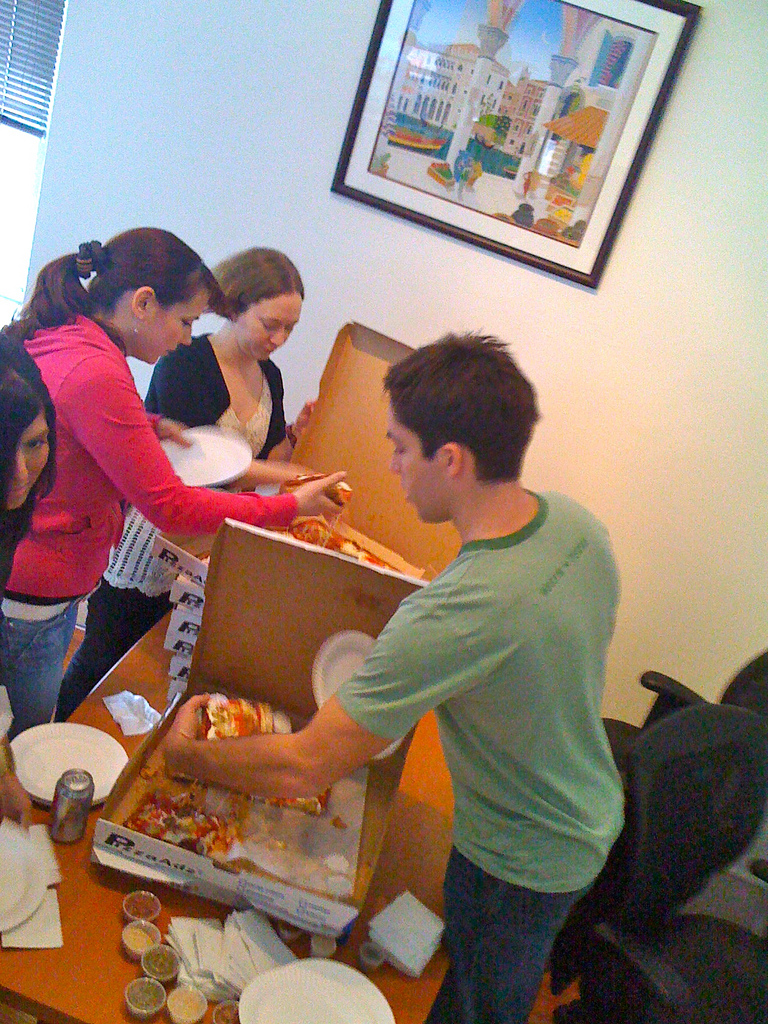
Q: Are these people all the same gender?
A: No, they are both male and female.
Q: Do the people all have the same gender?
A: No, they are both male and female.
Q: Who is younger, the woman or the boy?
A: The boy is younger than the woman.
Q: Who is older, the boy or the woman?
A: The woman is older than the boy.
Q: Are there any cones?
A: No, there are no cones.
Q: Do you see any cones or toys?
A: No, there are no cones or toys.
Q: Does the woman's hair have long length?
A: Yes, the hair is long.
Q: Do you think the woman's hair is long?
A: Yes, the hair is long.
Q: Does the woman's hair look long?
A: Yes, the hair is long.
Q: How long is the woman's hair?
A: The hair is long.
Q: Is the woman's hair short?
A: No, the hair is long.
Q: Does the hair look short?
A: No, the hair is long.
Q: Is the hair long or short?
A: The hair is long.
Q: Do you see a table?
A: Yes, there is a table.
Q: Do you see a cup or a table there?
A: Yes, there is a table.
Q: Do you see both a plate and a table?
A: Yes, there are both a table and a plate.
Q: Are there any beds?
A: No, there are no beds.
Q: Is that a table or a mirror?
A: That is a table.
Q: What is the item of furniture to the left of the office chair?
A: The piece of furniture is a table.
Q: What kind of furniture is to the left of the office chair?
A: The piece of furniture is a table.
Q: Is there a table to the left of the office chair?
A: Yes, there is a table to the left of the office chair.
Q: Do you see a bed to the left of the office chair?
A: No, there is a table to the left of the office chair.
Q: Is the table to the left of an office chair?
A: Yes, the table is to the left of an office chair.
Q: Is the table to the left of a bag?
A: No, the table is to the left of an office chair.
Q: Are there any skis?
A: No, there are no skis.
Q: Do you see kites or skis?
A: No, there are no skis or kites.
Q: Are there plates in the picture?
A: Yes, there is a plate.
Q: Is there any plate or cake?
A: Yes, there is a plate.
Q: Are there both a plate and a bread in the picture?
A: No, there is a plate but no breads.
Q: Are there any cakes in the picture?
A: No, there are no cakes.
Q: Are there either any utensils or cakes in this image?
A: No, there are no cakes or utensils.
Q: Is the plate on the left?
A: Yes, the plate is on the left of the image.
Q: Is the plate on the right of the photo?
A: No, the plate is on the left of the image.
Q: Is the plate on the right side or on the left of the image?
A: The plate is on the left of the image.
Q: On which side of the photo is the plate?
A: The plate is on the left of the image.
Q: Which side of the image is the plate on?
A: The plate is on the left of the image.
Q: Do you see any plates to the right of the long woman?
A: Yes, there is a plate to the right of the woman.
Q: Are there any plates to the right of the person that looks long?
A: Yes, there is a plate to the right of the woman.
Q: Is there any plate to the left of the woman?
A: No, the plate is to the right of the woman.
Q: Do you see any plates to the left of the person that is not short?
A: No, the plate is to the right of the woman.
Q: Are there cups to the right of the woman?
A: No, there is a plate to the right of the woman.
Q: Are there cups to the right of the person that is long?
A: No, there is a plate to the right of the woman.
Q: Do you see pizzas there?
A: Yes, there is a pizza.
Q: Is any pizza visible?
A: Yes, there is a pizza.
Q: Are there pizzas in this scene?
A: Yes, there is a pizza.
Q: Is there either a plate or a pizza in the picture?
A: Yes, there is a pizza.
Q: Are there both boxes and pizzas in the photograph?
A: Yes, there are both a pizza and a box.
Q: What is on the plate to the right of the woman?
A: The pizza is on the plate.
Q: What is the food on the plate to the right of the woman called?
A: The food is a pizza.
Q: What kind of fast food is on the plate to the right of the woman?
A: The food is a pizza.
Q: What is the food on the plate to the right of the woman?
A: The food is a pizza.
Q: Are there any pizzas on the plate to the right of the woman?
A: Yes, there is a pizza on the plate.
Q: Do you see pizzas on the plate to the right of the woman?
A: Yes, there is a pizza on the plate.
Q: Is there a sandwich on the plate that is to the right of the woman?
A: No, there is a pizza on the plate.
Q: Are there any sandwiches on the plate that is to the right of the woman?
A: No, there is a pizza on the plate.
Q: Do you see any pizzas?
A: Yes, there is a pizza.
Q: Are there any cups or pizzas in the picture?
A: Yes, there is a pizza.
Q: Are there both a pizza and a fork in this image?
A: No, there is a pizza but no forks.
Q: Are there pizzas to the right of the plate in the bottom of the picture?
A: Yes, there is a pizza to the right of the plate.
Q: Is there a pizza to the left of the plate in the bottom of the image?
A: No, the pizza is to the right of the plate.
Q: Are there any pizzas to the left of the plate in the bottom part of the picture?
A: No, the pizza is to the right of the plate.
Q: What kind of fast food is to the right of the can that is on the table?
A: The food is a pizza.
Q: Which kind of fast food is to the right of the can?
A: The food is a pizza.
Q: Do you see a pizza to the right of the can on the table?
A: Yes, there is a pizza to the right of the can.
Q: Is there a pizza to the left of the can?
A: No, the pizza is to the right of the can.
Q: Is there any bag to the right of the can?
A: No, there is a pizza to the right of the can.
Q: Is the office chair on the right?
A: Yes, the office chair is on the right of the image.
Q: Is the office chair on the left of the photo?
A: No, the office chair is on the right of the image.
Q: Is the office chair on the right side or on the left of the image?
A: The office chair is on the right of the image.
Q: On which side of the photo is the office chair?
A: The office chair is on the right of the image.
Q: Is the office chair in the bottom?
A: Yes, the office chair is in the bottom of the image.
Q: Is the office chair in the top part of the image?
A: No, the office chair is in the bottom of the image.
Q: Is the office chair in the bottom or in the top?
A: The office chair is in the bottom of the image.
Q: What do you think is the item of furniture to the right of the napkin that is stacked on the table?
A: The piece of furniture is an office chair.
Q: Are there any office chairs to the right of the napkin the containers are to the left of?
A: Yes, there is an office chair to the right of the napkin.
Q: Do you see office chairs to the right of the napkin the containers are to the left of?
A: Yes, there is an office chair to the right of the napkin.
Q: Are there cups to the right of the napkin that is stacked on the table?
A: No, there is an office chair to the right of the napkin.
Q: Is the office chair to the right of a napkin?
A: Yes, the office chair is to the right of a napkin.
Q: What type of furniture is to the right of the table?
A: The piece of furniture is an office chair.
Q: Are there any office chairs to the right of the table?
A: Yes, there is an office chair to the right of the table.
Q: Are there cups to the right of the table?
A: No, there is an office chair to the right of the table.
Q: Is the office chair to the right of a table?
A: Yes, the office chair is to the right of a table.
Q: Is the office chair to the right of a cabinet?
A: No, the office chair is to the right of a table.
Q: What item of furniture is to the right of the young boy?
A: The piece of furniture is an office chair.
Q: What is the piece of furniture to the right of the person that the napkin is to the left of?
A: The piece of furniture is an office chair.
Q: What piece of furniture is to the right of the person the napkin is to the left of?
A: The piece of furniture is an office chair.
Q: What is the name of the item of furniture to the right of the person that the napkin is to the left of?
A: The piece of furniture is an office chair.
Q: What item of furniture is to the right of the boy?
A: The piece of furniture is an office chair.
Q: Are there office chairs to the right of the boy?
A: Yes, there is an office chair to the right of the boy.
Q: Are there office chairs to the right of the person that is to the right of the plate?
A: Yes, there is an office chair to the right of the boy.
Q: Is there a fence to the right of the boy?
A: No, there is an office chair to the right of the boy.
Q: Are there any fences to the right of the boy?
A: No, there is an office chair to the right of the boy.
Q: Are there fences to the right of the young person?
A: No, there is an office chair to the right of the boy.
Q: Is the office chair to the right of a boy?
A: Yes, the office chair is to the right of a boy.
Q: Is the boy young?
A: Yes, the boy is young.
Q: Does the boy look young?
A: Yes, the boy is young.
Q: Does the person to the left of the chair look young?
A: Yes, the boy is young.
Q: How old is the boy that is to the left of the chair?
A: The boy is young.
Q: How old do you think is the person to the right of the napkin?
A: The boy is young.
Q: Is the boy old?
A: No, the boy is young.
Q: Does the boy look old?
A: No, the boy is young.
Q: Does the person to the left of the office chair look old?
A: No, the boy is young.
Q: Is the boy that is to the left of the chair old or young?
A: The boy is young.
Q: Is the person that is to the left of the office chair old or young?
A: The boy is young.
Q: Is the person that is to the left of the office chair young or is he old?
A: The boy is young.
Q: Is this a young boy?
A: Yes, this is a young boy.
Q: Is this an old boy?
A: No, this is a young boy.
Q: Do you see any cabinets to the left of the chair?
A: No, there is a boy to the left of the chair.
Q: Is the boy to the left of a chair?
A: Yes, the boy is to the left of a chair.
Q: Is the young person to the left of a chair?
A: Yes, the boy is to the left of a chair.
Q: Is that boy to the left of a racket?
A: No, the boy is to the left of a chair.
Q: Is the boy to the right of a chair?
A: No, the boy is to the left of a chair.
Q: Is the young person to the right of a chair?
A: No, the boy is to the left of a chair.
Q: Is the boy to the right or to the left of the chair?
A: The boy is to the left of the chair.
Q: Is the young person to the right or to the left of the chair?
A: The boy is to the left of the chair.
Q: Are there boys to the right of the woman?
A: Yes, there is a boy to the right of the woman.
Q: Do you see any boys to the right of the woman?
A: Yes, there is a boy to the right of the woman.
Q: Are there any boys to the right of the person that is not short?
A: Yes, there is a boy to the right of the woman.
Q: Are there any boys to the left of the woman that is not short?
A: No, the boy is to the right of the woman.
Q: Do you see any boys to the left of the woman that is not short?
A: No, the boy is to the right of the woman.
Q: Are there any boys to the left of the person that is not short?
A: No, the boy is to the right of the woman.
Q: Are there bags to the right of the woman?
A: No, there is a boy to the right of the woman.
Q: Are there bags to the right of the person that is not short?
A: No, there is a boy to the right of the woman.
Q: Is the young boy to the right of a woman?
A: Yes, the boy is to the right of a woman.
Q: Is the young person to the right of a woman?
A: Yes, the boy is to the right of a woman.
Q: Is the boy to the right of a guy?
A: No, the boy is to the right of a woman.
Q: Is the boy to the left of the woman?
A: No, the boy is to the right of the woman.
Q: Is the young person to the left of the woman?
A: No, the boy is to the right of the woman.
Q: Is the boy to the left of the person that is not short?
A: No, the boy is to the right of the woman.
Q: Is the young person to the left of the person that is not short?
A: No, the boy is to the right of the woman.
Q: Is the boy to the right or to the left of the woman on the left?
A: The boy is to the right of the woman.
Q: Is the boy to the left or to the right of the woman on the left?
A: The boy is to the right of the woman.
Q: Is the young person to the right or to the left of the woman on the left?
A: The boy is to the right of the woman.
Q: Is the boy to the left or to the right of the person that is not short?
A: The boy is to the right of the woman.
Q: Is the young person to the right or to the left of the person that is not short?
A: The boy is to the right of the woman.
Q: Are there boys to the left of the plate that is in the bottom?
A: No, the boy is to the right of the plate.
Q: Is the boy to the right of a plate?
A: Yes, the boy is to the right of a plate.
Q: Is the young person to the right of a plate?
A: Yes, the boy is to the right of a plate.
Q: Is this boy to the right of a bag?
A: No, the boy is to the right of a plate.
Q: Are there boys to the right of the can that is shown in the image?
A: Yes, there is a boy to the right of the can.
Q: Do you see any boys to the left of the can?
A: No, the boy is to the right of the can.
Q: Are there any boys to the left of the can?
A: No, the boy is to the right of the can.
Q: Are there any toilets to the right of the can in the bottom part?
A: No, there is a boy to the right of the can.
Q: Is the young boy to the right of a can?
A: Yes, the boy is to the right of a can.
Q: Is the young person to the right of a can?
A: Yes, the boy is to the right of a can.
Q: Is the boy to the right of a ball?
A: No, the boy is to the right of a can.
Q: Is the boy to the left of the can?
A: No, the boy is to the right of the can.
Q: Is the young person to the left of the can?
A: No, the boy is to the right of the can.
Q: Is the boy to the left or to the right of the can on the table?
A: The boy is to the right of the can.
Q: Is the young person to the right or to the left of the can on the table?
A: The boy is to the right of the can.